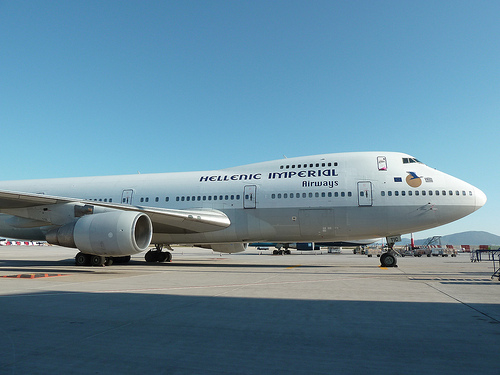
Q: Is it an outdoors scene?
A: Yes, it is outdoors.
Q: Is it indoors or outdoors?
A: It is outdoors.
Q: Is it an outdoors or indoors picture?
A: It is outdoors.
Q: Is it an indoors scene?
A: No, it is outdoors.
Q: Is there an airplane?
A: Yes, there is an airplane.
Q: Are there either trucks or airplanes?
A: Yes, there is an airplane.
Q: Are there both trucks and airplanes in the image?
A: No, there is an airplane but no trucks.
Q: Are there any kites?
A: No, there are no kites.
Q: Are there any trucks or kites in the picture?
A: No, there are no kites or trucks.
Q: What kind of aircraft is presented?
A: The aircraft is an airplane.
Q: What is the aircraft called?
A: The aircraft is an airplane.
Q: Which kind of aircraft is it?
A: The aircraft is an airplane.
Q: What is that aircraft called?
A: This is an airplane.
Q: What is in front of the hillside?
A: The airplane is in front of the hillside.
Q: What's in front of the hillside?
A: The airplane is in front of the hillside.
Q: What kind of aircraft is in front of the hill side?
A: The aircraft is an airplane.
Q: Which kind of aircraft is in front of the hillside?
A: The aircraft is an airplane.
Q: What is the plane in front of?
A: The plane is in front of the hillside.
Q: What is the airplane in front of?
A: The plane is in front of the hillside.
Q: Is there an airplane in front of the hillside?
A: Yes, there is an airplane in front of the hillside.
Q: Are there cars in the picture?
A: No, there are no cars.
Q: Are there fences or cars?
A: No, there are no cars or fences.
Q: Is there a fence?
A: No, there are no fences.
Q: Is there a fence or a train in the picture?
A: No, there are no fences or trains.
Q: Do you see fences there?
A: No, there are no fences.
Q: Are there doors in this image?
A: Yes, there is a door.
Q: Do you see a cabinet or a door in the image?
A: Yes, there is a door.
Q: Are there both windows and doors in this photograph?
A: Yes, there are both a door and a window.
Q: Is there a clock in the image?
A: No, there are no clocks.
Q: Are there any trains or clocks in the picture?
A: No, there are no clocks or trains.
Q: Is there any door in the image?
A: Yes, there is a door.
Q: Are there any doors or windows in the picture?
A: Yes, there is a door.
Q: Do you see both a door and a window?
A: Yes, there are both a door and a window.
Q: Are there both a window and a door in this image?
A: Yes, there are both a door and a window.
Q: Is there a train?
A: No, there are no trains.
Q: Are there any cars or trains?
A: No, there are no trains or cars.